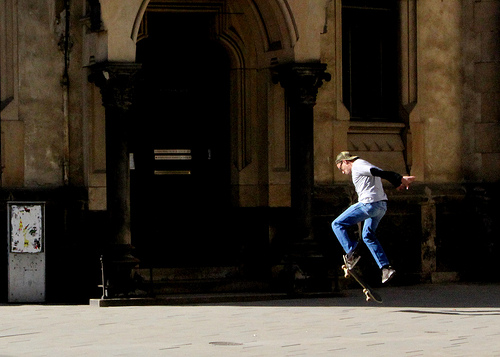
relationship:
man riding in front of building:
[327, 150, 413, 286] [1, 1, 481, 288]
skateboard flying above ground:
[339, 262, 384, 305] [0, 287, 484, 355]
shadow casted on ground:
[390, 303, 485, 316] [0, 287, 484, 355]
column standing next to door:
[86, 60, 142, 298] [133, 56, 223, 263]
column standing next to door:
[270, 59, 330, 292] [133, 56, 223, 263]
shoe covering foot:
[379, 264, 397, 284] [379, 265, 394, 282]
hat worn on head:
[331, 150, 359, 163] [334, 147, 352, 177]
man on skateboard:
[327, 150, 413, 286] [341, 260, 383, 305]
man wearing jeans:
[327, 150, 413, 286] [328, 200, 387, 268]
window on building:
[338, 0, 406, 120] [2, 2, 499, 308]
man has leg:
[327, 150, 413, 286] [363, 220, 388, 268]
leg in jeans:
[363, 220, 388, 268] [329, 200, 390, 271]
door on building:
[132, 7, 249, 282] [2, 2, 499, 308]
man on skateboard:
[327, 150, 413, 286] [339, 256, 384, 306]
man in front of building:
[327, 150, 413, 286] [1, 1, 481, 288]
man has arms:
[327, 150, 413, 286] [371, 166, 416, 192]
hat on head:
[333, 147, 360, 161] [332, 149, 355, 179]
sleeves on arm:
[363, 168, 403, 185] [355, 158, 416, 188]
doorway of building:
[119, 25, 259, 287] [1, 1, 481, 288]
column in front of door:
[87, 59, 154, 309] [127, 69, 233, 295]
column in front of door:
[267, 60, 330, 291] [127, 69, 233, 295]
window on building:
[338, 0, 406, 123] [1, 1, 481, 288]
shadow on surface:
[126, 284, 483, 314] [2, 288, 480, 355]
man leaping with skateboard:
[327, 150, 413, 286] [339, 262, 384, 305]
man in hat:
[327, 150, 413, 286] [329, 149, 361, 163]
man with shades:
[327, 150, 413, 286] [335, 160, 344, 176]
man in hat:
[321, 141, 416, 285] [331, 150, 359, 163]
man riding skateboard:
[321, 141, 416, 285] [342, 258, 386, 310]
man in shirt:
[327, 150, 413, 286] [346, 151, 390, 203]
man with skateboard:
[327, 150, 413, 286] [336, 255, 387, 305]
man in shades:
[327, 150, 413, 286] [335, 160, 344, 172]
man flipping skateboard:
[327, 150, 413, 286] [335, 255, 386, 311]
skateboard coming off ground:
[339, 262, 384, 305] [0, 287, 484, 355]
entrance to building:
[130, 70, 238, 266] [1, 1, 481, 288]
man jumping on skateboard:
[327, 150, 413, 286] [333, 257, 390, 305]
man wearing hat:
[327, 150, 413, 286] [333, 149, 360, 164]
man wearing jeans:
[327, 150, 413, 286] [328, 201, 395, 270]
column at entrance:
[267, 60, 330, 291] [130, 36, 238, 267]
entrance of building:
[130, 36, 238, 267] [1, 1, 481, 288]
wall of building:
[412, 4, 466, 187] [1, 1, 481, 288]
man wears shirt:
[321, 141, 416, 285] [348, 156, 388, 205]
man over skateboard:
[327, 150, 413, 286] [341, 254, 375, 301]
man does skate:
[327, 150, 413, 286] [326, 147, 417, 305]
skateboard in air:
[333, 251, 376, 301] [290, 118, 462, 316]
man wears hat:
[327, 150, 413, 286] [331, 150, 359, 163]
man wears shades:
[327, 150, 413, 286] [335, 160, 344, 176]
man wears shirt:
[327, 150, 413, 286] [348, 156, 391, 206]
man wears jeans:
[321, 141, 416, 285] [329, 200, 390, 271]